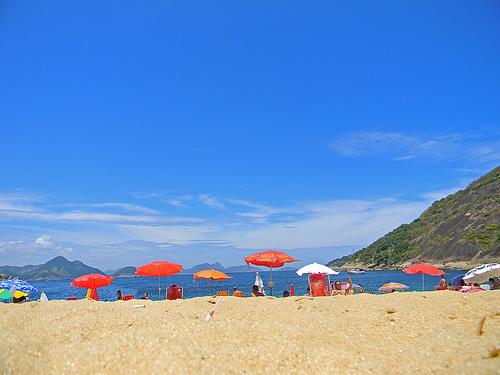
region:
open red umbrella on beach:
[138, 252, 185, 292]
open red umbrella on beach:
[65, 266, 113, 294]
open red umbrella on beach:
[198, 262, 240, 282]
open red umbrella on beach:
[245, 249, 280, 274]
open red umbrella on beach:
[391, 258, 433, 280]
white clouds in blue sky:
[24, 31, 106, 102]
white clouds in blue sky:
[48, 185, 119, 235]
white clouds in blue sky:
[138, 213, 193, 250]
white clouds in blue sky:
[222, 192, 269, 236]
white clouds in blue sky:
[287, 205, 335, 240]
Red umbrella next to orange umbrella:
[132, 258, 184, 300]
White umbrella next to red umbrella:
[292, 259, 342, 279]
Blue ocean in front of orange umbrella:
[0, 268, 479, 296]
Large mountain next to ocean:
[315, 161, 499, 276]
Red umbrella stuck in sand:
[68, 268, 115, 304]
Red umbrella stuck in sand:
[135, 257, 185, 301]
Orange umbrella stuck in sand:
[188, 264, 235, 296]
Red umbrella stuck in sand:
[242, 243, 298, 295]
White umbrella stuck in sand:
[294, 256, 341, 293]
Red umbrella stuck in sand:
[402, 259, 448, 288]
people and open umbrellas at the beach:
[0, 242, 496, 312]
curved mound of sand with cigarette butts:
[0, 290, 485, 365]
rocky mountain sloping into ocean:
[315, 161, 495, 271]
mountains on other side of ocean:
[0, 252, 291, 272]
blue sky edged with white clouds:
[5, 15, 495, 260]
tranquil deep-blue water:
[17, 271, 472, 297]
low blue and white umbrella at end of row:
[0, 271, 37, 301]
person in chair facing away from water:
[290, 245, 357, 292]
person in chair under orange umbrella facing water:
[135, 255, 180, 297]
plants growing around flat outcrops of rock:
[326, 158, 496, 313]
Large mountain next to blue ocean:
[318, 158, 498, 265]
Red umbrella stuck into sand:
[68, 270, 117, 302]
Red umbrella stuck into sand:
[135, 258, 185, 303]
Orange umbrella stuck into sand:
[190, 263, 233, 299]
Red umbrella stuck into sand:
[242, 247, 301, 297]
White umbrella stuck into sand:
[292, 258, 342, 295]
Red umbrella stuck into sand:
[400, 261, 445, 291]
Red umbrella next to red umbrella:
[69, 268, 114, 300]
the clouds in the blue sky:
[0, 1, 498, 256]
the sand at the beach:
[0, 288, 499, 374]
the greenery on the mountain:
[321, 163, 498, 272]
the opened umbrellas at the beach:
[0, 249, 499, 300]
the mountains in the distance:
[0, 254, 298, 279]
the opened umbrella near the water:
[135, 260, 183, 299]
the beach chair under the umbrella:
[164, 284, 183, 301]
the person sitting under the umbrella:
[250, 284, 263, 297]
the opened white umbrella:
[295, 262, 337, 276]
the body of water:
[17, 269, 498, 301]